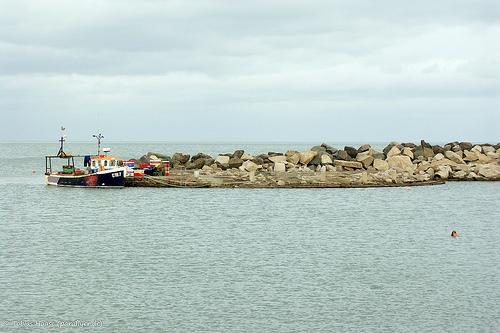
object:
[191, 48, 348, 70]
clouds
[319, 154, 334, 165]
rock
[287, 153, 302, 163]
rock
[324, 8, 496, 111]
sky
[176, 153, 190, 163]
rock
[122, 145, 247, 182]
land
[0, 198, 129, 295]
water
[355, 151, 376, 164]
rock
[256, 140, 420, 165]
land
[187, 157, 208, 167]
rock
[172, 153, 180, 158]
rock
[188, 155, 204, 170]
rock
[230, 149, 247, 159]
rock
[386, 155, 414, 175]
rock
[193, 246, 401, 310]
water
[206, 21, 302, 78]
sky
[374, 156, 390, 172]
rock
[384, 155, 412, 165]
rock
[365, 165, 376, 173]
rock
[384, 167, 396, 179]
rock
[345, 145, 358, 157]
rock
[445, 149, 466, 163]
rock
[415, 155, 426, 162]
rock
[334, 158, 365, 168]
rock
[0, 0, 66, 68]
clouds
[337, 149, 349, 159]
gray rock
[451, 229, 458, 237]
object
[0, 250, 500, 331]
water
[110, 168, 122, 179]
letters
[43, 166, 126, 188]
boat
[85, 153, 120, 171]
boat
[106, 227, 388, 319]
water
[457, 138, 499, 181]
island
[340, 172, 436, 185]
land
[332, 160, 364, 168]
rock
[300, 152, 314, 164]
rock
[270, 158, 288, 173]
rock